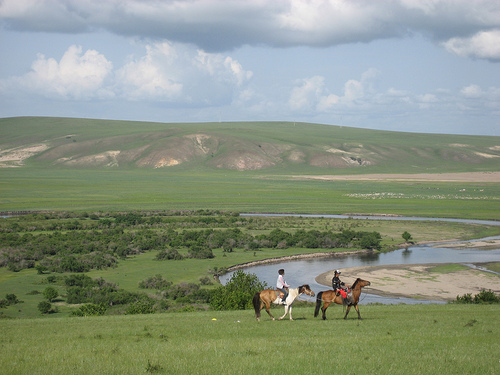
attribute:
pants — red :
[329, 276, 353, 309]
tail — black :
[314, 280, 338, 336]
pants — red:
[334, 280, 351, 307]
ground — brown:
[350, 234, 484, 324]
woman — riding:
[259, 262, 291, 286]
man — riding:
[320, 254, 355, 294]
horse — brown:
[316, 278, 390, 316]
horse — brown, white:
[255, 281, 314, 321]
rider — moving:
[248, 270, 305, 293]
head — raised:
[350, 267, 390, 289]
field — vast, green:
[39, 169, 469, 219]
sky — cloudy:
[51, 9, 470, 85]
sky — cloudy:
[12, 8, 496, 123]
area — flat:
[17, 167, 457, 224]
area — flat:
[43, 156, 451, 229]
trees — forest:
[39, 196, 283, 281]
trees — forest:
[40, 221, 276, 338]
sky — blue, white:
[185, 30, 482, 132]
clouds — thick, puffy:
[121, 17, 379, 54]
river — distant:
[245, 221, 475, 291]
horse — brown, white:
[255, 280, 315, 313]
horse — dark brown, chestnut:
[313, 276, 372, 319]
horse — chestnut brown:
[251, 280, 316, 321]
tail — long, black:
[311, 288, 323, 320]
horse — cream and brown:
[250, 281, 318, 318]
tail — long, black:
[252, 287, 262, 318]